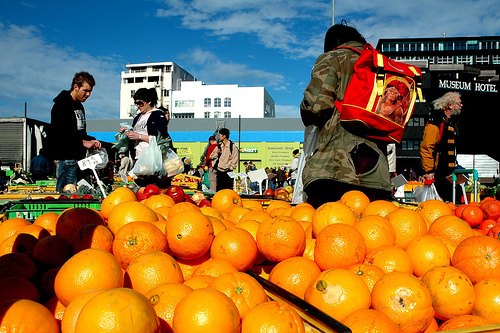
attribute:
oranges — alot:
[9, 171, 495, 324]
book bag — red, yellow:
[342, 45, 423, 143]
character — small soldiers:
[373, 86, 412, 119]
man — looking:
[45, 71, 110, 194]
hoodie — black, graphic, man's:
[46, 92, 96, 166]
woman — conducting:
[123, 86, 191, 188]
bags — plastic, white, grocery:
[134, 136, 184, 180]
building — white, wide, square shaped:
[119, 52, 279, 121]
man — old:
[421, 90, 472, 202]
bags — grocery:
[413, 178, 444, 203]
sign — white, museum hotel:
[434, 72, 500, 96]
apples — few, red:
[134, 181, 214, 207]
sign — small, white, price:
[76, 150, 115, 203]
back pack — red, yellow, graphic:
[342, 43, 427, 148]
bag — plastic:
[83, 146, 111, 169]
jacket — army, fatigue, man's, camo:
[299, 41, 408, 195]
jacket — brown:
[218, 139, 243, 174]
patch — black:
[346, 145, 384, 174]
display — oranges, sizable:
[2, 175, 498, 329]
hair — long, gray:
[433, 95, 460, 111]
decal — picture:
[374, 81, 415, 122]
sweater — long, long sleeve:
[47, 89, 96, 164]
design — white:
[76, 106, 90, 132]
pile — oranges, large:
[6, 175, 498, 322]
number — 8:
[80, 162, 87, 170]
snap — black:
[376, 69, 386, 79]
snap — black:
[414, 74, 425, 85]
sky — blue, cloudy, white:
[1, 0, 497, 117]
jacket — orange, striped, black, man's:
[419, 110, 463, 176]